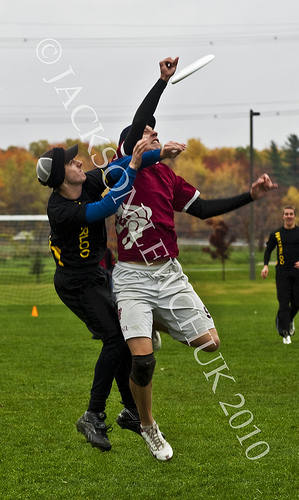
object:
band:
[35, 143, 77, 191]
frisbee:
[169, 51, 215, 89]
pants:
[52, 262, 139, 418]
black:
[202, 202, 216, 216]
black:
[103, 350, 124, 367]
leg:
[111, 262, 153, 430]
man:
[108, 53, 278, 463]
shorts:
[108, 258, 218, 344]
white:
[140, 220, 143, 224]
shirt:
[105, 153, 202, 266]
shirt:
[42, 186, 113, 276]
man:
[35, 137, 156, 451]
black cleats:
[98, 406, 108, 426]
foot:
[73, 399, 114, 451]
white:
[163, 447, 174, 453]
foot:
[129, 329, 172, 463]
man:
[262, 198, 298, 347]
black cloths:
[262, 226, 299, 337]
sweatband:
[45, 146, 66, 188]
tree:
[201, 218, 239, 280]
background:
[1, 94, 299, 289]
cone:
[29, 304, 39, 317]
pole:
[248, 108, 255, 281]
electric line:
[1, 113, 249, 118]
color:
[108, 139, 199, 263]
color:
[111, 258, 216, 345]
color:
[78, 223, 91, 257]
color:
[45, 232, 66, 269]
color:
[30, 301, 39, 316]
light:
[16, 35, 278, 132]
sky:
[7, 11, 297, 149]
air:
[1, 1, 297, 152]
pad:
[128, 346, 156, 386]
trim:
[180, 185, 201, 211]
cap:
[34, 144, 76, 191]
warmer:
[50, 156, 63, 213]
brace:
[127, 347, 156, 391]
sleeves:
[82, 166, 137, 226]